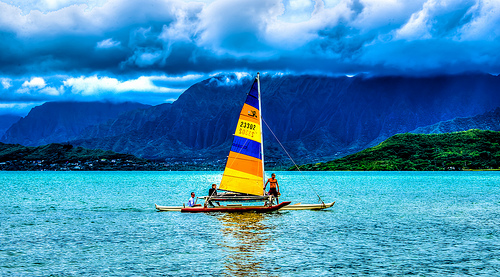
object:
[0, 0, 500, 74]
clouds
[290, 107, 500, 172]
hill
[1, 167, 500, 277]
water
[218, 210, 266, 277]
reflection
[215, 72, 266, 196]
sail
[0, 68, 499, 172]
island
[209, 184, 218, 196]
people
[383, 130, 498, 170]
grass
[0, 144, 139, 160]
grass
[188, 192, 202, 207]
man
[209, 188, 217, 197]
shirt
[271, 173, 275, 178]
head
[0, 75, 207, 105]
clouds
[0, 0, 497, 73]
sky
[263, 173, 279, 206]
man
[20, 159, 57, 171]
buildings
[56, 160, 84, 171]
buildings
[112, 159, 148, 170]
buildings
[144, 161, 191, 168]
buildings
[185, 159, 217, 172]
buildings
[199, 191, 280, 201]
boat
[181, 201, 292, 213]
boat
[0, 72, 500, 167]
mountains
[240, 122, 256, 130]
number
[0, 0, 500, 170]
background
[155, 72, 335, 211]
boat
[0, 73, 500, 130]
distance